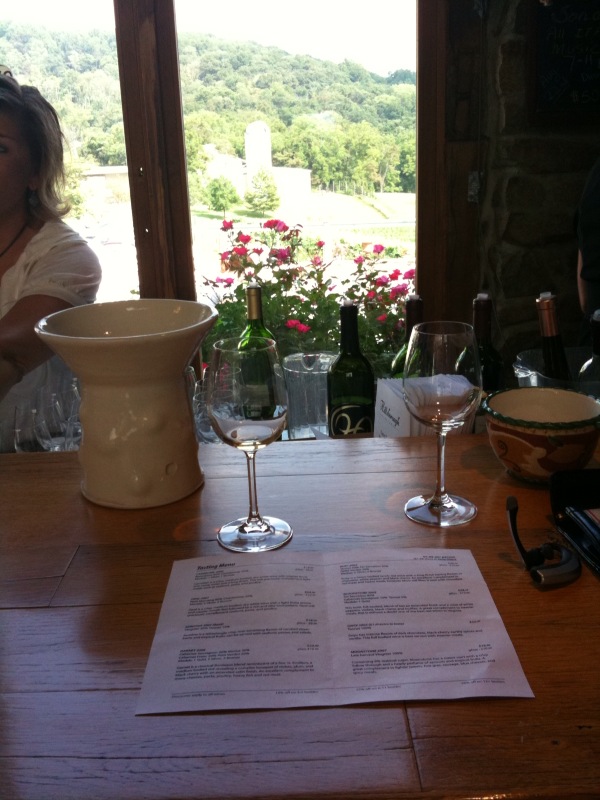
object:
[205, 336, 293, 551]
glass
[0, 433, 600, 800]
table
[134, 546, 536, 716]
menu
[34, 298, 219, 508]
bucket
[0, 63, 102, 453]
woman